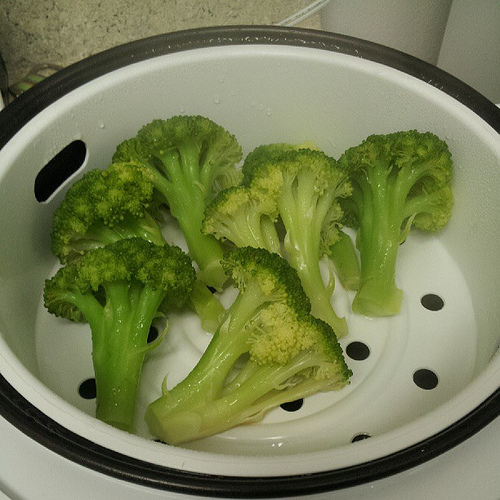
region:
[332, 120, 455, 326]
The broccoli is green.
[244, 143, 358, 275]
The broccoli is green.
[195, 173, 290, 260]
The broccoli is green.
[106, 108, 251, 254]
The broccoli is green.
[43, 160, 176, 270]
The broccoli is green.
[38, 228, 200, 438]
The broccoli is green.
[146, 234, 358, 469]
The broccoli is green.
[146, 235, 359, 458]
The broccoli is clean.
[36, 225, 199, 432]
The broccoli is clean.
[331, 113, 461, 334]
The broccoli is clean.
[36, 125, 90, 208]
hole in side of vegetable steamer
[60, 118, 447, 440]
steamed pieces of broccoli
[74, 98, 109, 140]
water drops on side of steamer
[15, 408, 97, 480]
black rim on vegetable steamer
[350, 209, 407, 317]
green stem on cooked broccoli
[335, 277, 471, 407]
steam holes in bottom of steamer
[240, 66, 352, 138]
wide coating on side of steamer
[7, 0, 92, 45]
top of kitchen counter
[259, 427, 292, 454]
reflection of light on vegetable steamer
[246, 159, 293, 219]
yellow broccoli florets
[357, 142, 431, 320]
broccoli in the bowl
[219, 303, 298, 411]
broccoli in the bowl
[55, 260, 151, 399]
broccoli in the bowl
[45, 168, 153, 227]
broccoli in the bowl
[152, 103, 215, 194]
broccoli in the bowl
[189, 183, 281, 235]
broccoli in the bowl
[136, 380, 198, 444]
stem of the broccoli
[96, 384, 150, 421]
stem of the broccoli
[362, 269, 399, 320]
stem of the broccoli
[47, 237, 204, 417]
A piece of broccoli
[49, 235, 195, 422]
Green broccoli in a bowl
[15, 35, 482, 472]
Broccoli in a bowl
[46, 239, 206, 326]
Head of a piece of broccoli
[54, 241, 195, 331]
Head of a piece of green broccoli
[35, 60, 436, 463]
The broccoli is green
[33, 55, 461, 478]
The broccoli is in a bowl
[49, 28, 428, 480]
The broccoli is wet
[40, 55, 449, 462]
The broccoli has been washed off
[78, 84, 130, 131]
Water is in the bowl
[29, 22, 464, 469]
brocolli in a bowl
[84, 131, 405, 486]
brocolli in a steamed bowl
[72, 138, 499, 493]
a bowl with brocolli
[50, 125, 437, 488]
a steam bowl with brocolli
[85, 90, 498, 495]
steam brocolli in a bowl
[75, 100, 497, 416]
steammed brocolli in a steam bowl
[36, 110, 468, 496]
steamed green brocolli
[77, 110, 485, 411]
brocolli that has been steamed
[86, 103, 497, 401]
green brocolli that has steamed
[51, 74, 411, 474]
a bowl for steaming